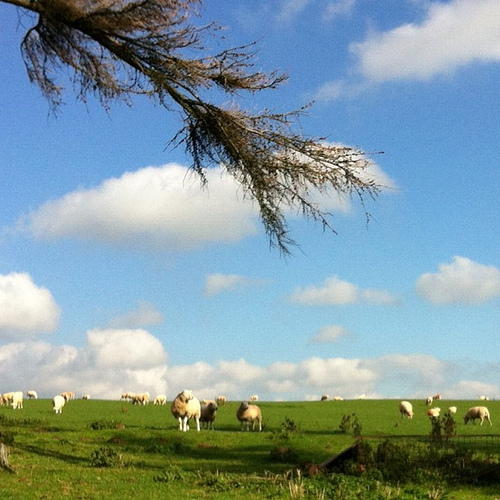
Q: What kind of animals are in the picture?
A: Cows.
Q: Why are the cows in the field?
A: Eating.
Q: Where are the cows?
A: Field.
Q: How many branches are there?
A: One.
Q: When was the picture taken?
A: Day time.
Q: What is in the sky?
A: Clouds.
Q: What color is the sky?
A: Blue.